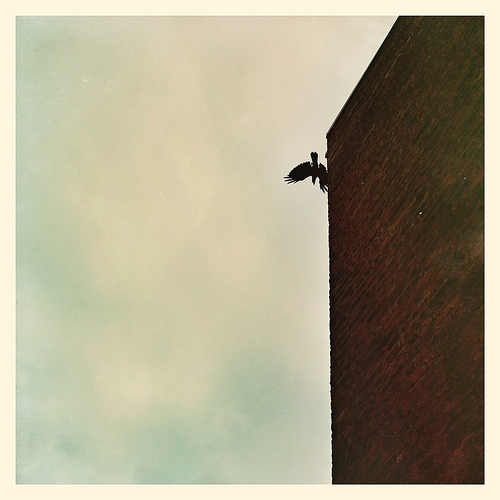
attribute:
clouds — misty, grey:
[41, 49, 234, 408]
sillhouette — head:
[247, 191, 329, 269]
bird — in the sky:
[282, 145, 334, 195]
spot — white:
[414, 203, 423, 222]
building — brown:
[319, 19, 477, 482]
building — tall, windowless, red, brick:
[331, 19, 483, 480]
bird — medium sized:
[278, 148, 329, 198]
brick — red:
[342, 250, 423, 332]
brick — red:
[347, 233, 382, 265]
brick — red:
[394, 285, 423, 316]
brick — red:
[371, 243, 422, 306]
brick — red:
[409, 250, 438, 291]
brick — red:
[381, 301, 411, 341]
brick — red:
[401, 293, 432, 327]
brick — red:
[380, 270, 426, 318]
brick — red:
[373, 403, 423, 440]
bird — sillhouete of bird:
[272, 140, 331, 194]